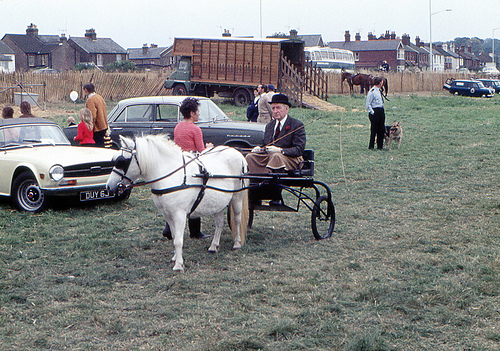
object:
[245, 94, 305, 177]
man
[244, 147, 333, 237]
cart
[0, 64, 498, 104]
fence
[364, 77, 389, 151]
man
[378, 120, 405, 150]
dog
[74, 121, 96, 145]
shirt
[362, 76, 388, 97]
horse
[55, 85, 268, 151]
car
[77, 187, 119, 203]
plate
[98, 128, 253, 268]
white horse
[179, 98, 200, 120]
hair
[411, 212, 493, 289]
grass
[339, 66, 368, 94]
horse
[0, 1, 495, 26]
sky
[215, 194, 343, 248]
chart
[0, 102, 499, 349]
ground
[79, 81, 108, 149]
man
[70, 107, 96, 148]
girl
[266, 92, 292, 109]
hat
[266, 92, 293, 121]
head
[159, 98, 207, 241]
lady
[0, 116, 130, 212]
car